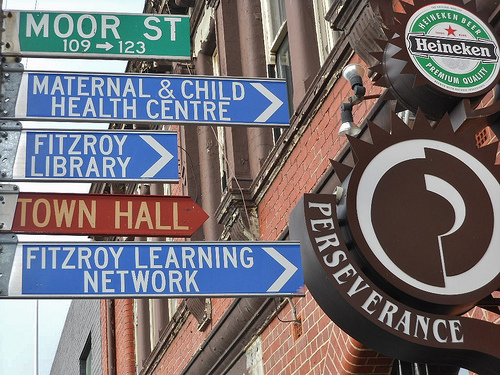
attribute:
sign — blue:
[20, 124, 190, 184]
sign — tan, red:
[1, 185, 213, 242]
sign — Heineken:
[397, 3, 497, 91]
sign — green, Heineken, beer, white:
[366, 0, 498, 120]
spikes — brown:
[303, 106, 499, 167]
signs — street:
[8, 14, 305, 312]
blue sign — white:
[12, 127, 180, 180]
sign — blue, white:
[21, 244, 301, 300]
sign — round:
[402, 18, 486, 78]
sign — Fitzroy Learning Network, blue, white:
[1, 245, 296, 299]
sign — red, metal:
[12, 193, 199, 235]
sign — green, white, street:
[2, 5, 192, 60]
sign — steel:
[23, 79, 285, 122]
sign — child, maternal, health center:
[19, 71, 290, 130]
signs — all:
[11, 23, 306, 350]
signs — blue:
[10, 65, 297, 187]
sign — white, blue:
[1, 239, 307, 303]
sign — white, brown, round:
[279, 102, 499, 311]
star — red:
[446, 16, 458, 43]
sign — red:
[3, 190, 207, 238]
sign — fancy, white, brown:
[269, 144, 492, 341]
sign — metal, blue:
[18, 131, 179, 179]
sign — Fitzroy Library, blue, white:
[0, 120, 191, 184]